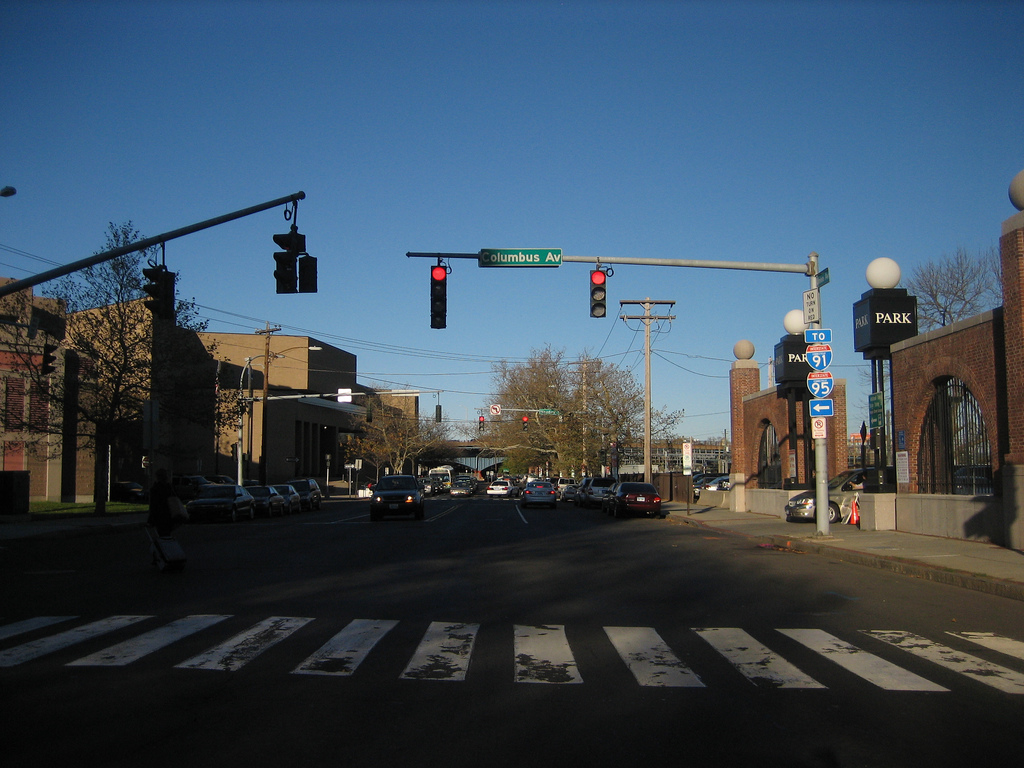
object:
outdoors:
[0, 232, 1024, 768]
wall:
[399, 401, 415, 441]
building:
[356, 384, 424, 483]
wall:
[269, 349, 308, 389]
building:
[191, 328, 358, 483]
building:
[381, 389, 420, 478]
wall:
[391, 414, 413, 445]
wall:
[339, 370, 419, 492]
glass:
[892, 363, 1018, 536]